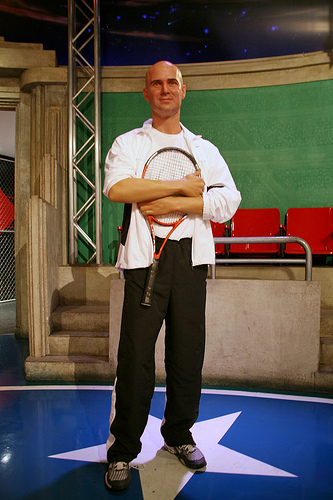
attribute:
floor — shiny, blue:
[2, 382, 331, 498]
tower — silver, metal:
[66, 3, 101, 266]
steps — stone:
[25, 301, 110, 378]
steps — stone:
[22, 300, 113, 382]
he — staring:
[102, 60, 241, 488]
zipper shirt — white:
[102, 118, 241, 269]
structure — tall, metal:
[52, 3, 116, 264]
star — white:
[44, 406, 301, 498]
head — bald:
[137, 60, 189, 117]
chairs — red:
[116, 207, 331, 265]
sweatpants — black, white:
[114, 246, 259, 430]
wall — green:
[83, 81, 328, 225]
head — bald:
[142, 61, 185, 83]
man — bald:
[99, 57, 241, 490]